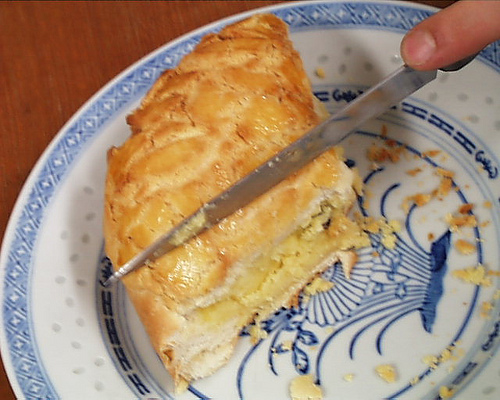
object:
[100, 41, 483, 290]
knife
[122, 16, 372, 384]
pie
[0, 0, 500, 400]
plate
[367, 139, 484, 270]
crumbs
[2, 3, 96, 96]
table